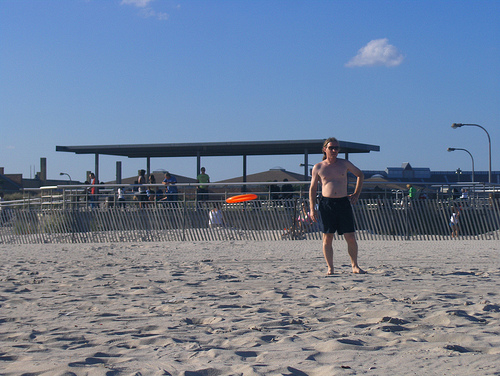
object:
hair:
[321, 137, 340, 161]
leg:
[341, 215, 359, 260]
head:
[322, 137, 339, 160]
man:
[161, 173, 177, 207]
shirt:
[163, 176, 178, 192]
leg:
[322, 214, 337, 265]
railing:
[0, 181, 311, 206]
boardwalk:
[40, 182, 297, 212]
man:
[196, 166, 211, 211]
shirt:
[197, 174, 210, 189]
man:
[308, 136, 368, 274]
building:
[346, 163, 500, 198]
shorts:
[318, 193, 357, 235]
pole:
[59, 172, 72, 185]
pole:
[300, 162, 312, 176]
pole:
[447, 147, 475, 183]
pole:
[451, 123, 493, 183]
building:
[1, 158, 82, 189]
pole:
[455, 167, 463, 183]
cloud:
[344, 37, 407, 69]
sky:
[0, 0, 499, 170]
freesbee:
[225, 193, 257, 202]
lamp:
[450, 121, 464, 129]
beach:
[0, 227, 499, 375]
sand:
[2, 230, 499, 375]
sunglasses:
[325, 145, 340, 149]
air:
[0, 0, 499, 199]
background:
[0, 166, 500, 207]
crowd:
[85, 167, 470, 239]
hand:
[346, 192, 359, 205]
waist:
[321, 189, 348, 202]